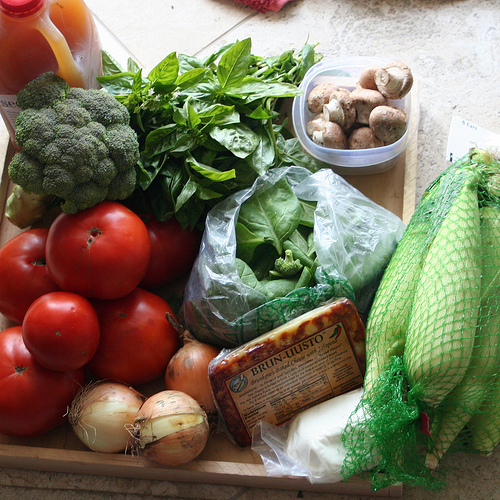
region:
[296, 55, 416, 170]
A transparent container of mushrooms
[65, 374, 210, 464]
Two onions still in their peel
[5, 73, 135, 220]
A head of broccoli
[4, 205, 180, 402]
A pile of large, red tomatoes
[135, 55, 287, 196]
Leafy, green vegetables in a pile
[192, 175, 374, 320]
A plastic bag of leafy vegetables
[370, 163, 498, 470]
A bundle of corn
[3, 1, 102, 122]
Half of a gallon of iced tea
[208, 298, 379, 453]
Cheese wrapped in plastic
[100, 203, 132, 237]
Skin of a tomato reflecting light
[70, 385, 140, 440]
a cooking onion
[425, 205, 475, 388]
a raw maize in a plastic bag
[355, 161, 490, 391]
a bunch of maize packed in a net bag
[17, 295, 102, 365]
a ripe tomatoe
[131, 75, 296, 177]
a bunch of green vegetables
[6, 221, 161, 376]
a bunch of ripe tomatoes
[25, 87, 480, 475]
a collection of cooking vegetables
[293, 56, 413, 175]
mushrooms in plastic bowl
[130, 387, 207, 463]
onion with split skin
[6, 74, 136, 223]
florets of broccoli bunch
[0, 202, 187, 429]
pile of red tomatoes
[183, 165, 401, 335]
bag of spinach leaves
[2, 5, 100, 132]
plastic jug of liquid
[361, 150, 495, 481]
green net bag over corn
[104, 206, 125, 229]
light reflection on skin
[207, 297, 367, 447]
sealed plastic bag of food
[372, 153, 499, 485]
Sweet corn in a mesh bag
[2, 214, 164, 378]
Some ripe tomatoes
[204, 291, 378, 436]
Package of baked cheese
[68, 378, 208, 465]
A couple of white onions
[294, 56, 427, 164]
A container of edible mushrooms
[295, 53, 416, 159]
A container of mushrooms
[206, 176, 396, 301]
A bag of spinach leaves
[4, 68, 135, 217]
A head of broccoli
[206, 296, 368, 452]
A package of cheese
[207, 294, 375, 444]
A small package of baked cheese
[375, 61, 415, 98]
mushroom on top of container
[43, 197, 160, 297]
tomatoe next to broccoli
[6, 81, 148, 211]
broccoli next to tomato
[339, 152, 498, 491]
corn inside a net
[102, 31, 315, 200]
vegetable greens next to broccoli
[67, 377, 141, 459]
oniions next to tomato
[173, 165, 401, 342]
spinach leaves in a bag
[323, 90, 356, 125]
mushroom in a container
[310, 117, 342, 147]
mushroom in a container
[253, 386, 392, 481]
cheese beside corn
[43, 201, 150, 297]
Large round tomato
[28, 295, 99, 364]
Large round tomato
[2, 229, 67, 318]
Large round tomato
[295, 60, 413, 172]
a bowl of mushrooms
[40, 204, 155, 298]
a large red tomato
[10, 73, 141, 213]
a large head of broccoli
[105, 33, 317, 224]
a bunch of green lettuce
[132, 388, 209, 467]
a large onion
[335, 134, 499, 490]
a bunch of corn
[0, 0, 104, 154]
a bottle of juice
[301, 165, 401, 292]
a clear plastic food bag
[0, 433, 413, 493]
a wooden tray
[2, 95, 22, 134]
a white sticker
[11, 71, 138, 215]
large green bunch of broccoli